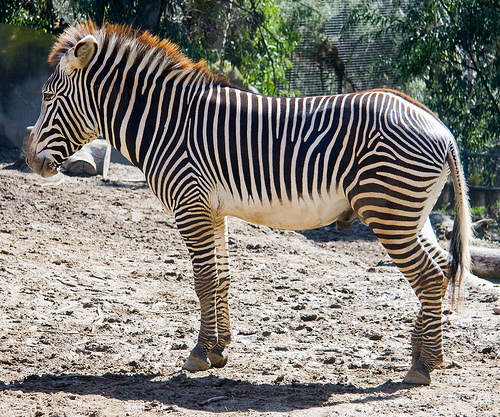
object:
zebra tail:
[432, 127, 478, 311]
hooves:
[178, 354, 214, 373]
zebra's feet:
[206, 346, 228, 368]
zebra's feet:
[399, 365, 433, 387]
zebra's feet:
[417, 345, 445, 368]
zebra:
[22, 15, 478, 390]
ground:
[0, 165, 498, 416]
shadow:
[3, 363, 426, 409]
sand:
[0, 170, 498, 415]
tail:
[444, 142, 479, 318]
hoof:
[399, 367, 432, 384]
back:
[111, 20, 448, 143]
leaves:
[263, 21, 276, 31]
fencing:
[281, 0, 423, 99]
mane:
[38, 17, 228, 85]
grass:
[0, 16, 52, 82]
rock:
[0, 67, 45, 147]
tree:
[182, 0, 293, 95]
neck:
[84, 40, 185, 166]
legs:
[167, 202, 239, 378]